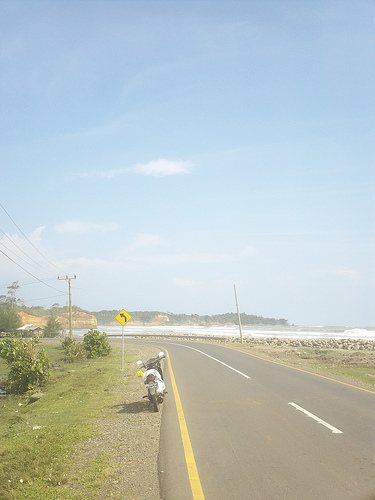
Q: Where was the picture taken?
A: It was taken at the highway.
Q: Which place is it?
A: It is a highway.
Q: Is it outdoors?
A: Yes, it is outdoors.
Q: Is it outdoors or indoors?
A: It is outdoors.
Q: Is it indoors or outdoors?
A: It is outdoors.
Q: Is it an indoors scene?
A: No, it is outdoors.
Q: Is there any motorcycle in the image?
A: Yes, there is a motorcycle.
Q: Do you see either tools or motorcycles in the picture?
A: Yes, there is a motorcycle.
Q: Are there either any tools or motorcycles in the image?
A: Yes, there is a motorcycle.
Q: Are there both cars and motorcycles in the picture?
A: No, there is a motorcycle but no cars.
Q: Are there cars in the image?
A: No, there are no cars.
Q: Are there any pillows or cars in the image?
A: No, there are no cars or pillows.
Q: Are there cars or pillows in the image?
A: No, there are no cars or pillows.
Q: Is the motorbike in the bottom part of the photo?
A: Yes, the motorbike is in the bottom of the image.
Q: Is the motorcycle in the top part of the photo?
A: No, the motorcycle is in the bottom of the image.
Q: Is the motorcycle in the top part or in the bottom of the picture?
A: The motorcycle is in the bottom of the image.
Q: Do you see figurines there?
A: No, there are no figurines.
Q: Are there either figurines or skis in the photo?
A: No, there are no figurines or skis.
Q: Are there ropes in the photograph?
A: No, there are no ropes.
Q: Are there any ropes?
A: No, there are no ropes.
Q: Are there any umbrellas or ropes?
A: No, there are no ropes or umbrellas.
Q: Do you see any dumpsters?
A: No, there are no dumpsters.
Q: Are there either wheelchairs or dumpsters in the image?
A: No, there are no dumpsters or wheelchairs.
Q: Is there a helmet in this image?
A: No, there are no helmets.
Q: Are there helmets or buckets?
A: No, there are no helmets or buckets.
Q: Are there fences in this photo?
A: No, there are no fences.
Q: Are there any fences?
A: No, there are no fences.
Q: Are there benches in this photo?
A: No, there are no benches.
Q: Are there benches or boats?
A: No, there are no benches or boats.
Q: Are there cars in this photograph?
A: No, there are no cars.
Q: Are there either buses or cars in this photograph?
A: No, there are no cars or buses.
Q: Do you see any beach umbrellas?
A: No, there are no beach umbrellas.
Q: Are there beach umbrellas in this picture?
A: No, there are no beach umbrellas.